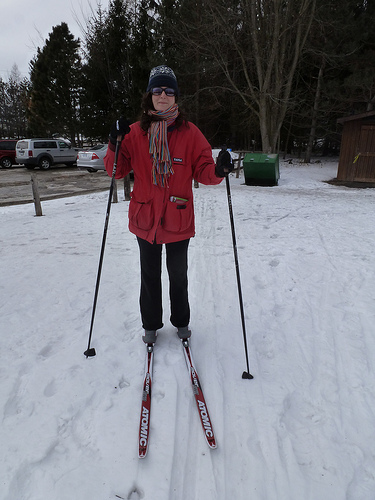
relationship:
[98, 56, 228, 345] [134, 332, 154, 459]
person in ski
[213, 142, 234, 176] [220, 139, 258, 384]
hand holding ski pole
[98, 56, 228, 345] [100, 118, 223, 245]
person in a coat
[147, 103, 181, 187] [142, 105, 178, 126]
scarf on a persons neck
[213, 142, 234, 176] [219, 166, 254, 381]
hand grips poles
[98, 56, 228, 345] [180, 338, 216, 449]
person on ski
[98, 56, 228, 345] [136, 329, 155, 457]
person on ski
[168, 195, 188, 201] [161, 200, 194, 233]
book inside pocket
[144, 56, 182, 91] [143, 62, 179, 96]
design on hat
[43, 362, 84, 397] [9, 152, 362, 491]
footprint on snow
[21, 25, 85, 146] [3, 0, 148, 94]
tree in front of sky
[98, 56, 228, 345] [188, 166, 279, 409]
person holding poles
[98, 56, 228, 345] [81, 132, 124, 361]
person holding ski pole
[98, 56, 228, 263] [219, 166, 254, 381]
person holding poles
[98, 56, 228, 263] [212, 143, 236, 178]
person has hand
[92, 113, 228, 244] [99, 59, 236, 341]
coat on person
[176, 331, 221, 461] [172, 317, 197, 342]
ski on foot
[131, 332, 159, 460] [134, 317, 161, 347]
ski on foot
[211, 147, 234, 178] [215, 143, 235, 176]
glove on hand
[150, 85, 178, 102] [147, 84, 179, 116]
sunglasses on face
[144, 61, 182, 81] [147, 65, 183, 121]
design on head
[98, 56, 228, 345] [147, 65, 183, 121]
person has head